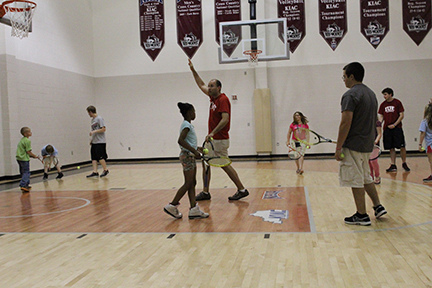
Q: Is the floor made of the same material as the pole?
A: No, the floor is made of wood and the pole is made of metal.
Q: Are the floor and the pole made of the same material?
A: No, the floor is made of wood and the pole is made of metal.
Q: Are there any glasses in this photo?
A: No, there are no glasses.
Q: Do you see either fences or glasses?
A: No, there are no glasses or fences.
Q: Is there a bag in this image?
A: No, there are no bags.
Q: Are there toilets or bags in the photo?
A: No, there are no bags or toilets.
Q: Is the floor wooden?
A: Yes, the floor is wooden.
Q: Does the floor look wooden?
A: Yes, the floor is wooden.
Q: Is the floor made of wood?
A: Yes, the floor is made of wood.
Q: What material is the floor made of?
A: The floor is made of wood.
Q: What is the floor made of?
A: The floor is made of wood.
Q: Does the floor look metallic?
A: No, the floor is wooden.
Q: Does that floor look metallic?
A: No, the floor is wooden.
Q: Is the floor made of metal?
A: No, the floor is made of wood.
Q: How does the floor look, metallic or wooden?
A: The floor is wooden.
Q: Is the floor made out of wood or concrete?
A: The floor is made of wood.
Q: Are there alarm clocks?
A: No, there are no alarm clocks.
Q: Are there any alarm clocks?
A: No, there are no alarm clocks.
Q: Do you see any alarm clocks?
A: No, there are no alarm clocks.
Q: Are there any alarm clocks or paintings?
A: No, there are no alarm clocks or paintings.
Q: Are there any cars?
A: No, there are no cars.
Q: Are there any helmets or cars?
A: No, there are no cars or helmets.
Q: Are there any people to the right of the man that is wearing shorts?
A: Yes, there is a person to the right of the man.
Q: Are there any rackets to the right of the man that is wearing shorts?
A: No, there is a person to the right of the man.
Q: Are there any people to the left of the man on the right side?
A: Yes, there is a person to the left of the man.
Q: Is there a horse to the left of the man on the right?
A: No, there is a person to the left of the man.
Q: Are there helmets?
A: No, there are no helmets.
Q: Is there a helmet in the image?
A: No, there are no helmets.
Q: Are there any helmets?
A: No, there are no helmets.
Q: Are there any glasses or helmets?
A: No, there are no helmets or glasses.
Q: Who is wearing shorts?
A: The man is wearing shorts.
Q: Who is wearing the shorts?
A: The man is wearing shorts.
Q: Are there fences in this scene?
A: No, there are no fences.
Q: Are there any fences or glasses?
A: No, there are no fences or glasses.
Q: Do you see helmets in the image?
A: No, there are no helmets.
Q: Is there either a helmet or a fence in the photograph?
A: No, there are no helmets or fences.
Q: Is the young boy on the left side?
A: Yes, the boy is on the left of the image.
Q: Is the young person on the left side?
A: Yes, the boy is on the left of the image.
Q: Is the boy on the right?
A: No, the boy is on the left of the image.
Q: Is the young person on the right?
A: No, the boy is on the left of the image.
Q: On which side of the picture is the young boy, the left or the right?
A: The boy is on the left of the image.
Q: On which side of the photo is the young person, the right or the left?
A: The boy is on the left of the image.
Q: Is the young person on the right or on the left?
A: The boy is on the left of the image.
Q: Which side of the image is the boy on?
A: The boy is on the left of the image.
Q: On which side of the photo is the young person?
A: The boy is on the left of the image.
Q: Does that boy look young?
A: Yes, the boy is young.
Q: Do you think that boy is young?
A: Yes, the boy is young.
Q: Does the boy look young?
A: Yes, the boy is young.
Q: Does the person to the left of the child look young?
A: Yes, the boy is young.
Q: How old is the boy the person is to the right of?
A: The boy is young.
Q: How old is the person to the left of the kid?
A: The boy is young.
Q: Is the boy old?
A: No, the boy is young.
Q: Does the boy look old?
A: No, the boy is young.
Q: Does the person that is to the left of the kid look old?
A: No, the boy is young.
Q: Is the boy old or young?
A: The boy is young.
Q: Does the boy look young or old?
A: The boy is young.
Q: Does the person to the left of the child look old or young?
A: The boy is young.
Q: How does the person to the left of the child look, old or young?
A: The boy is young.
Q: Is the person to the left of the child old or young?
A: The boy is young.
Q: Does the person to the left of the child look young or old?
A: The boy is young.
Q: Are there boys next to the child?
A: Yes, there is a boy next to the child.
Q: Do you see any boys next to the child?
A: Yes, there is a boy next to the child.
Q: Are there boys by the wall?
A: Yes, there is a boy by the wall.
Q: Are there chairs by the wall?
A: No, there is a boy by the wall.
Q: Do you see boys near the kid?
A: Yes, there is a boy near the kid.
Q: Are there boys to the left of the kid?
A: Yes, there is a boy to the left of the kid.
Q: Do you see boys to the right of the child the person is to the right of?
A: No, the boy is to the left of the kid.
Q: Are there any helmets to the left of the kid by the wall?
A: No, there is a boy to the left of the child.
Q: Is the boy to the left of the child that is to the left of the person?
A: Yes, the boy is to the left of the kid.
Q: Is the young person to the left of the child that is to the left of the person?
A: Yes, the boy is to the left of the kid.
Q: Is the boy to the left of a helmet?
A: No, the boy is to the left of the kid.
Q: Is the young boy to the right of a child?
A: No, the boy is to the left of a child.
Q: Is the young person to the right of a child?
A: No, the boy is to the left of a child.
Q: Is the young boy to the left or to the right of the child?
A: The boy is to the left of the child.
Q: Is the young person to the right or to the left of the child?
A: The boy is to the left of the child.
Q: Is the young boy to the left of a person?
A: Yes, the boy is to the left of a person.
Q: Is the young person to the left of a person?
A: Yes, the boy is to the left of a person.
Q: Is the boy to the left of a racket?
A: No, the boy is to the left of a person.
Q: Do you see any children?
A: Yes, there is a child.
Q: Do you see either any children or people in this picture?
A: Yes, there is a child.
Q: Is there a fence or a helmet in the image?
A: No, there are no fences or helmets.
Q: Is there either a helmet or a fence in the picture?
A: No, there are no fences or helmets.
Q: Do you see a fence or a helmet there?
A: No, there are no fences or helmets.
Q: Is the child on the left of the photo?
A: Yes, the child is on the left of the image.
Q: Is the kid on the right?
A: No, the kid is on the left of the image.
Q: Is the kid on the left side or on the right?
A: The kid is on the left of the image.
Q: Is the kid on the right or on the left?
A: The kid is on the left of the image.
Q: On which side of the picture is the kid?
A: The kid is on the left of the image.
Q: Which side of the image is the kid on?
A: The kid is on the left of the image.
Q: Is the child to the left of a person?
A: Yes, the child is to the left of a person.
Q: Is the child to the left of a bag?
A: No, the child is to the left of a person.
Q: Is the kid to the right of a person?
A: No, the kid is to the left of a person.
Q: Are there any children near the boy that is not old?
A: Yes, there is a child near the boy.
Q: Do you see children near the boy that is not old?
A: Yes, there is a child near the boy.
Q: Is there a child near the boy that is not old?
A: Yes, there is a child near the boy.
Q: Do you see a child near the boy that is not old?
A: Yes, there is a child near the boy.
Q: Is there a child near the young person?
A: Yes, there is a child near the boy.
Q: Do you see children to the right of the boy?
A: Yes, there is a child to the right of the boy.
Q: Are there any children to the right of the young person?
A: Yes, there is a child to the right of the boy.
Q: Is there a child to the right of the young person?
A: Yes, there is a child to the right of the boy.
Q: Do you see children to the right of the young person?
A: Yes, there is a child to the right of the boy.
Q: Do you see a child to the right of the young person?
A: Yes, there is a child to the right of the boy.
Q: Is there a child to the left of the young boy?
A: No, the child is to the right of the boy.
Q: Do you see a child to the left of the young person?
A: No, the child is to the right of the boy.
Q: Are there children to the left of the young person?
A: No, the child is to the right of the boy.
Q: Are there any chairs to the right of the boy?
A: No, there is a child to the right of the boy.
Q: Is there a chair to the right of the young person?
A: No, there is a child to the right of the boy.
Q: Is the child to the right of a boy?
A: Yes, the child is to the right of a boy.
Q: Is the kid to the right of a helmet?
A: No, the kid is to the right of a boy.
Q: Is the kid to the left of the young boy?
A: No, the kid is to the right of the boy.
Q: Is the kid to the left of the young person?
A: No, the kid is to the right of the boy.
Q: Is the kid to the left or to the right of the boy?
A: The kid is to the right of the boy.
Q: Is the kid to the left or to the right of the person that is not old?
A: The kid is to the right of the boy.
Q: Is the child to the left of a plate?
A: No, the child is to the left of a person.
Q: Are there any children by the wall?
A: Yes, there is a child by the wall.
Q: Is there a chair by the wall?
A: No, there is a child by the wall.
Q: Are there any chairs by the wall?
A: No, there is a child by the wall.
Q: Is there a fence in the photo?
A: No, there are no fences.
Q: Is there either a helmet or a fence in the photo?
A: No, there are no fences or helmets.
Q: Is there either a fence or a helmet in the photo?
A: No, there are no fences or helmets.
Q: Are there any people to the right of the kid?
A: Yes, there is a person to the right of the kid.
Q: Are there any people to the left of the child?
A: No, the person is to the right of the child.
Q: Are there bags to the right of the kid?
A: No, there is a person to the right of the kid.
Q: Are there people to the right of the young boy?
A: Yes, there is a person to the right of the boy.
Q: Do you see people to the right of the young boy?
A: Yes, there is a person to the right of the boy.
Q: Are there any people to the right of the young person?
A: Yes, there is a person to the right of the boy.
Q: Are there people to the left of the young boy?
A: No, the person is to the right of the boy.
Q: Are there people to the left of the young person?
A: No, the person is to the right of the boy.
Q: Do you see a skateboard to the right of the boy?
A: No, there is a person to the right of the boy.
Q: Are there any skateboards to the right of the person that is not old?
A: No, there is a person to the right of the boy.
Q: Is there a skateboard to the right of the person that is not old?
A: No, there is a person to the right of the boy.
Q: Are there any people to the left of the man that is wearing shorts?
A: Yes, there is a person to the left of the man.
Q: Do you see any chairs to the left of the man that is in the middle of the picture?
A: No, there is a person to the left of the man.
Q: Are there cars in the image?
A: No, there are no cars.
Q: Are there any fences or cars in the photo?
A: No, there are no cars or fences.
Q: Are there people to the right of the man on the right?
A: Yes, there is a person to the right of the man.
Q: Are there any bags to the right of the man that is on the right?
A: No, there is a person to the right of the man.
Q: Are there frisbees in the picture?
A: No, there are no frisbees.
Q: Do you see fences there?
A: No, there are no fences.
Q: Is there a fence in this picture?
A: No, there are no fences.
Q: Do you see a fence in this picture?
A: No, there are no fences.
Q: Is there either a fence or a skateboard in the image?
A: No, there are no fences or skateboards.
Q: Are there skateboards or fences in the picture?
A: No, there are no fences or skateboards.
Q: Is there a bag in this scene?
A: No, there are no bags.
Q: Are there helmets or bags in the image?
A: No, there are no bags or helmets.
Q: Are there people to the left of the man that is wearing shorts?
A: Yes, there is a person to the left of the man.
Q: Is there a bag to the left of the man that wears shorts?
A: No, there is a person to the left of the man.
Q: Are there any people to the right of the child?
A: Yes, there is a person to the right of the child.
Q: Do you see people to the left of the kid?
A: No, the person is to the right of the kid.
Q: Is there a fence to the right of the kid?
A: No, there is a person to the right of the kid.